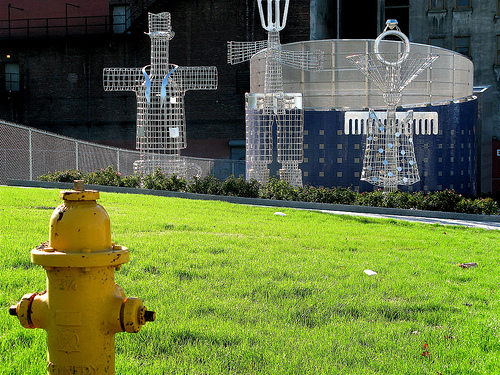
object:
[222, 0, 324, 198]
statues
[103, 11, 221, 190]
figures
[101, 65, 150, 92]
arms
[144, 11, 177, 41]
hat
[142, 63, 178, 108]
tie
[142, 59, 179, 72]
neck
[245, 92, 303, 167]
trousers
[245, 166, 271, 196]
shoes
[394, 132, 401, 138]
dots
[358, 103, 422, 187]
skirt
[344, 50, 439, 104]
arms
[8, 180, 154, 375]
hydrant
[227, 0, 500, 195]
wall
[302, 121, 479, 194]
squares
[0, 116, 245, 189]
fence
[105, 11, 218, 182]
sculpture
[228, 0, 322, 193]
structure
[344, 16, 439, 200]
sculpture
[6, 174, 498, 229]
path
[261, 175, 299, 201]
bushes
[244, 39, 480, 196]
metal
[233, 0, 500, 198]
building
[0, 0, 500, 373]
park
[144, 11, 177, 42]
top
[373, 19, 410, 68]
ring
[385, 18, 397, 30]
diamond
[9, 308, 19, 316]
bolts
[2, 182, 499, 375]
grass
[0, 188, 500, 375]
slope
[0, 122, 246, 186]
chain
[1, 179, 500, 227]
curb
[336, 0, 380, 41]
windows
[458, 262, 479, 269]
rock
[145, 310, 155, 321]
bolt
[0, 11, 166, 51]
railing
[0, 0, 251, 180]
building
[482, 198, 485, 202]
blooms